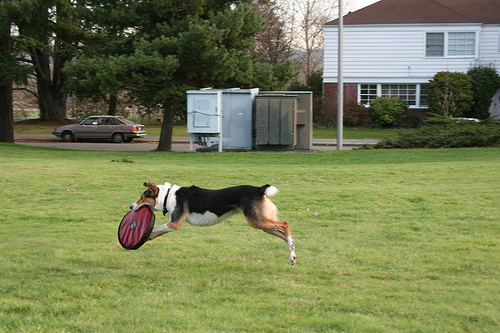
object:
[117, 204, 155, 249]
frisbee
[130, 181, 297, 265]
dog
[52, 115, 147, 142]
car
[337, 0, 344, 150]
pole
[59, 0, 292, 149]
tree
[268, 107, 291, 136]
grey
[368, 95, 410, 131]
bushes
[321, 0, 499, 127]
house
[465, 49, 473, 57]
windows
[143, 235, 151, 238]
black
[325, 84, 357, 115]
brick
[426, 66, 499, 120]
bush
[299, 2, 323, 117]
tree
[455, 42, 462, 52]
glass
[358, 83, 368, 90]
windows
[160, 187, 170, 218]
collar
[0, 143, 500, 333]
lawn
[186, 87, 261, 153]
dumpster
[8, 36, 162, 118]
building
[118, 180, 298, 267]
jumping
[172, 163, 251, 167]
air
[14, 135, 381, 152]
street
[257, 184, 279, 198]
tail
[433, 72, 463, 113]
tree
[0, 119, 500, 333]
ground